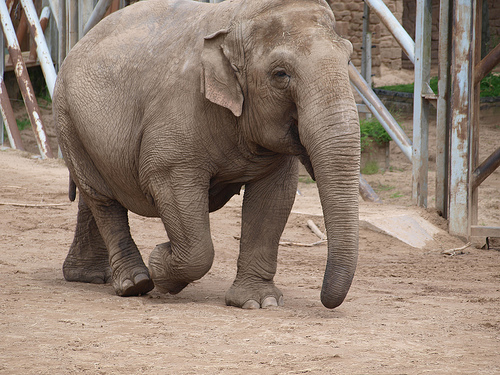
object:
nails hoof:
[109, 267, 155, 296]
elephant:
[51, 0, 363, 312]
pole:
[363, 0, 418, 64]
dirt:
[0, 106, 499, 374]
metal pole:
[448, 0, 477, 241]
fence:
[0, 0, 144, 167]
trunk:
[292, 63, 365, 309]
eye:
[270, 67, 293, 82]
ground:
[0, 106, 499, 374]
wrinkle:
[268, 76, 293, 91]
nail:
[241, 299, 263, 311]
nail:
[259, 295, 278, 309]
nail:
[277, 293, 287, 307]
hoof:
[223, 280, 286, 310]